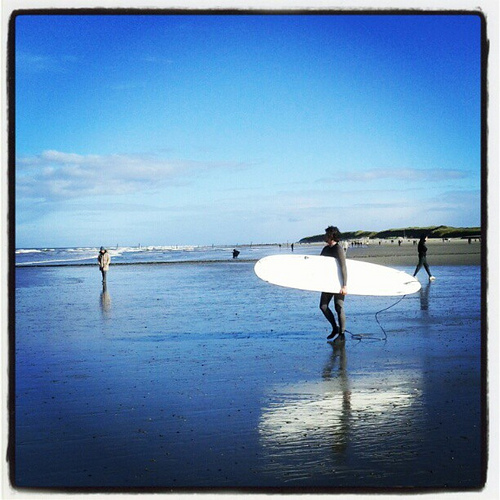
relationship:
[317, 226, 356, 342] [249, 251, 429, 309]
surfer carrying surfboard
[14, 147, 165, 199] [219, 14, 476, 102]
cloud in sky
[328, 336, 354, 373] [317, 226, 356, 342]
reflection of surfer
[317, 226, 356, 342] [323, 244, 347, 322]
surfer wearing wetsuit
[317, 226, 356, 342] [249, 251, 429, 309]
surfer has surfboard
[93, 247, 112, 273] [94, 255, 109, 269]
person wearing jacket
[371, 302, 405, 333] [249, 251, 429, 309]
rope on surfboard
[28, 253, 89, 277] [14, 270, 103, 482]
waves in ocean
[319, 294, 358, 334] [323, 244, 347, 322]
legs in wetsuit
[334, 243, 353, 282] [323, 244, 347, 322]
arm in wetsuit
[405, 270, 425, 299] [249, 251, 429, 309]
end of surfboard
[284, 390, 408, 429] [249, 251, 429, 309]
reflection of surfboard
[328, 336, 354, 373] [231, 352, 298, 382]
reflection on water